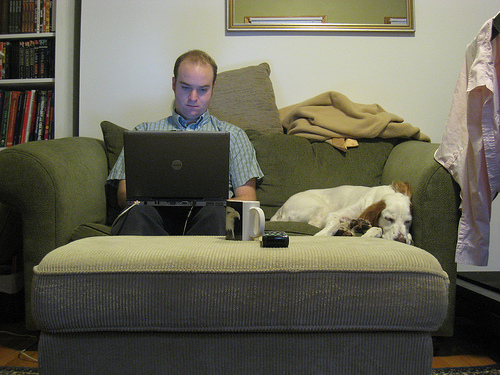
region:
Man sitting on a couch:
[120, 45, 267, 252]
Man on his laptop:
[115, 121, 255, 211]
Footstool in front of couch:
[35, 187, 481, 366]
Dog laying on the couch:
[274, 184, 439, 247]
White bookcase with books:
[6, 4, 76, 194]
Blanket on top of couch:
[274, 82, 492, 175]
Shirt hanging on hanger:
[430, 17, 498, 214]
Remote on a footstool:
[252, 215, 300, 265]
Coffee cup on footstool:
[225, 192, 270, 255]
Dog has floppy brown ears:
[284, 157, 422, 254]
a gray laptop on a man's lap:
[118, 127, 235, 208]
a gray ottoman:
[36, 233, 454, 369]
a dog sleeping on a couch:
[272, 181, 423, 248]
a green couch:
[4, 126, 463, 336]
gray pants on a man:
[112, 196, 240, 243]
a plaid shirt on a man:
[108, 110, 273, 194]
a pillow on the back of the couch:
[195, 50, 287, 147]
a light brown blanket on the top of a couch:
[277, 90, 441, 158]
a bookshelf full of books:
[0, 2, 83, 154]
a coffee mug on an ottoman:
[224, 196, 270, 238]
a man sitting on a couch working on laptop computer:
[94, 49, 280, 236]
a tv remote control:
[261, 230, 288, 247]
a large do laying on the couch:
[271, 182, 418, 241]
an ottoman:
[24, 230, 445, 370]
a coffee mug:
[226, 200, 264, 241]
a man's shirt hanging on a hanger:
[434, 12, 497, 267]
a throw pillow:
[213, 61, 278, 133]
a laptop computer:
[121, 127, 228, 206]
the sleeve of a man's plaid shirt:
[229, 124, 262, 185]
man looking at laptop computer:
[121, 47, 237, 242]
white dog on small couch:
[268, 163, 419, 255]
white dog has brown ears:
[332, 179, 413, 226]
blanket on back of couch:
[271, 78, 423, 153]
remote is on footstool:
[257, 230, 309, 261]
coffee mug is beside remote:
[212, 198, 269, 242]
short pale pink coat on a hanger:
[436, 6, 491, 268]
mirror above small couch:
[218, 1, 420, 49]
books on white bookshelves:
[7, 0, 73, 144]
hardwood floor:
[7, 330, 52, 372]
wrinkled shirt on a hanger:
[431, 1, 499, 287]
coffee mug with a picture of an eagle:
[212, 192, 266, 249]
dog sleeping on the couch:
[276, 174, 424, 259]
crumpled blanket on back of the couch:
[261, 77, 426, 162]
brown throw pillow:
[170, 42, 291, 141]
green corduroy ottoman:
[31, 206, 475, 372]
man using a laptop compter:
[91, 43, 262, 242]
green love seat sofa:
[6, 102, 499, 340]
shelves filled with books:
[1, 0, 62, 152]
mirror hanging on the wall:
[213, 1, 434, 48]